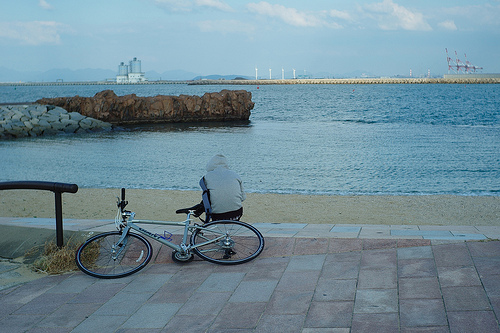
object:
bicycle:
[74, 186, 266, 278]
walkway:
[0, 242, 500, 333]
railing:
[0, 179, 80, 251]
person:
[197, 151, 246, 260]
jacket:
[199, 152, 247, 214]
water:
[365, 159, 455, 195]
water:
[309, 120, 381, 160]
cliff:
[0, 87, 258, 125]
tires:
[188, 219, 266, 266]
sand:
[290, 194, 388, 217]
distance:
[315, 66, 361, 84]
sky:
[0, 0, 500, 84]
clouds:
[299, 20, 308, 28]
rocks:
[101, 101, 110, 114]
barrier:
[0, 101, 120, 140]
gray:
[6, 109, 28, 123]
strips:
[312, 80, 316, 84]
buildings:
[128, 73, 141, 83]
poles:
[255, 68, 258, 80]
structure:
[116, 56, 146, 84]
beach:
[0, 187, 499, 226]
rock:
[198, 89, 257, 115]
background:
[0, 0, 499, 86]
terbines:
[443, 47, 466, 74]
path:
[0, 223, 500, 265]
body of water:
[296, 109, 382, 152]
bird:
[246, 50, 249, 52]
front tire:
[73, 229, 154, 280]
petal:
[179, 241, 191, 251]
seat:
[174, 203, 205, 218]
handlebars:
[116, 187, 130, 213]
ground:
[0, 183, 500, 333]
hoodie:
[205, 154, 228, 173]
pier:
[186, 78, 270, 85]